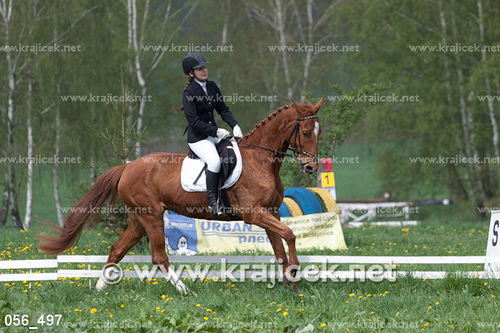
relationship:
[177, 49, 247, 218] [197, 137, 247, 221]
jockey wearing boots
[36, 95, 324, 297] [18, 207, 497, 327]
brown horse on field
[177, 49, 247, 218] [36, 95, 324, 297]
jockey riding brown horse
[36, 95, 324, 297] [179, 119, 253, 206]
brown horse with saddle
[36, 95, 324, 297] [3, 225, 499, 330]
brown horse in field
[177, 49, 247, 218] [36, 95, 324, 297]
jockey on brown horse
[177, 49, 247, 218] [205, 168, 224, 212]
jockey wearing riding boot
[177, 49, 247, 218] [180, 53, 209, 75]
jockey wearing helmet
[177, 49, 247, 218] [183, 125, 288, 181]
jockey sitting on saddle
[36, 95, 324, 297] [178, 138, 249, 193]
brown horse wearing saddle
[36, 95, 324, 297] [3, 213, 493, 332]
brown horse on grass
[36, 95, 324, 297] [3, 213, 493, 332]
brown horse walking on grass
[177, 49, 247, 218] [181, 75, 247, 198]
jockey wearing outfit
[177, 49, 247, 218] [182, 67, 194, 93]
jockey has hair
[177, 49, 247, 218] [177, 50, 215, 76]
jockey wearing helmet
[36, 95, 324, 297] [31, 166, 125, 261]
brown horse has tail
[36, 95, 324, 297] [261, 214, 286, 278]
brown horse has leg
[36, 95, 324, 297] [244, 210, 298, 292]
brown horse has leg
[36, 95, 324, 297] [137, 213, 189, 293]
brown horse has leg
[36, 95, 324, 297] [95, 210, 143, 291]
brown horse has leg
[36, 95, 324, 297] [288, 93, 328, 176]
brown horse has head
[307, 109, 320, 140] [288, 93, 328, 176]
spot on head